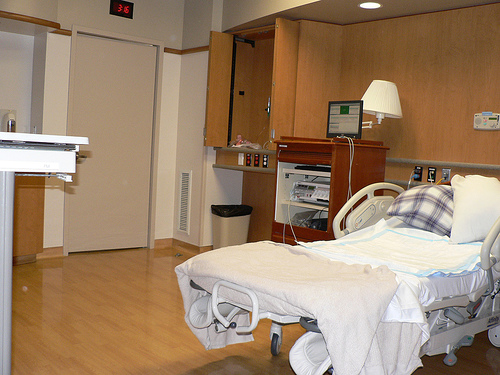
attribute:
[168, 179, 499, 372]
bed — adjustable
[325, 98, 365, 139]
monitor — lcd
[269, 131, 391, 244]
cabinet — large, wooden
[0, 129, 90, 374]
table — adjustable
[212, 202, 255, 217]
liner — black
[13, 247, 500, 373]
floor — wood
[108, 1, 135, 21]
clock — digital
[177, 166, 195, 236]
air vent — AC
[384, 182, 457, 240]
pillow case — plaid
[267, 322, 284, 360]
wheel — black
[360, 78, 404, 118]
shade — white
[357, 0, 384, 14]
light — recessed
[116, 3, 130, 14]
numbers — digital, red